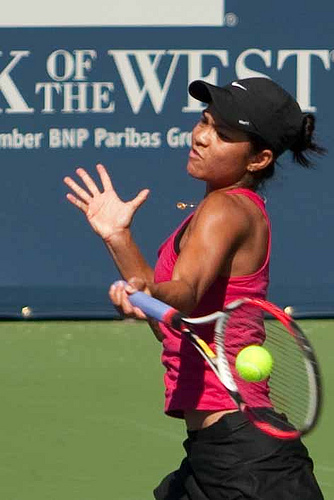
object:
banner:
[3, 4, 330, 320]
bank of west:
[1, 48, 332, 121]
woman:
[66, 78, 322, 498]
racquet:
[115, 281, 319, 436]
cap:
[188, 76, 307, 144]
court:
[8, 318, 329, 500]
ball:
[237, 344, 271, 382]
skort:
[150, 408, 323, 497]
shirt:
[146, 189, 272, 411]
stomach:
[181, 408, 239, 430]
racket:
[182, 327, 214, 362]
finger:
[95, 162, 112, 193]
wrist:
[102, 222, 134, 247]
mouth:
[186, 144, 210, 158]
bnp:
[43, 128, 89, 149]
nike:
[228, 77, 247, 91]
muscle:
[181, 188, 235, 297]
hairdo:
[255, 87, 333, 170]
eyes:
[193, 109, 214, 131]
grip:
[115, 282, 175, 324]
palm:
[67, 160, 147, 238]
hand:
[108, 277, 154, 324]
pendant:
[169, 199, 201, 212]